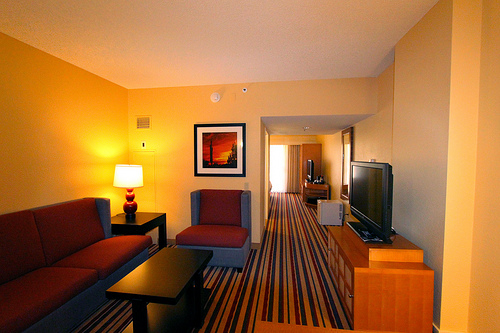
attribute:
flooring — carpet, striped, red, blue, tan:
[40, 190, 434, 332]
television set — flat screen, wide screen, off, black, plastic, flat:
[346, 160, 394, 246]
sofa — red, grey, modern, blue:
[3, 195, 151, 330]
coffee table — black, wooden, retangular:
[107, 247, 212, 332]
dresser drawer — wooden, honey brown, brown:
[324, 218, 436, 332]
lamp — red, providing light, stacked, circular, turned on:
[111, 164, 149, 218]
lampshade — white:
[112, 163, 145, 191]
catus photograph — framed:
[191, 124, 245, 177]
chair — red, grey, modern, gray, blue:
[175, 189, 253, 275]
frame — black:
[192, 121, 245, 179]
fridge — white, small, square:
[315, 196, 346, 228]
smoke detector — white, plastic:
[205, 90, 223, 105]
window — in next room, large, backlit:
[272, 148, 288, 198]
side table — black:
[108, 208, 167, 247]